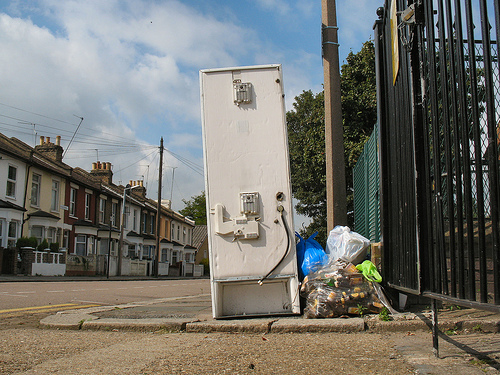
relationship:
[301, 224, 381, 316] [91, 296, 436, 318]
bag on sidewalk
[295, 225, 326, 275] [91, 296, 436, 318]
bag on sidewalk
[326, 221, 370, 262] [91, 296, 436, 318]
bag on sidewalk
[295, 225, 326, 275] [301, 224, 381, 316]
bag over bag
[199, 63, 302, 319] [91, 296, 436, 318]
box on sidewalk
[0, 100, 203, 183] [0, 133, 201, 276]
wires over homes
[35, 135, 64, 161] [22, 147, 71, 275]
chimney top of home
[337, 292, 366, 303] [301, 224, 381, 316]
bottle in bag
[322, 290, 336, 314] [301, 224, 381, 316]
bottle in bag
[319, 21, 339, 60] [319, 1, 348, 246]
sign strapped to pole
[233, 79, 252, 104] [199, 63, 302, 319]
control for box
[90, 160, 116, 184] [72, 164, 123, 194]
chimney on roof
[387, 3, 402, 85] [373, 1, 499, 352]
sign attached to fence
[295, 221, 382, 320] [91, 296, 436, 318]
trash on sidewalk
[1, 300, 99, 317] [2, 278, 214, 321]
line on street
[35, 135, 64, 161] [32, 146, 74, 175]
chimney on roof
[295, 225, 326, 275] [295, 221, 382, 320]
bag on pile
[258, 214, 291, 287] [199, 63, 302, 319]
cord on box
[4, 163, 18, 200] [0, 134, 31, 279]
window on home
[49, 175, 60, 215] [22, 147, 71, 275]
window on home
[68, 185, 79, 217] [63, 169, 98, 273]
window on home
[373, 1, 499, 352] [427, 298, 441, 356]
fence has support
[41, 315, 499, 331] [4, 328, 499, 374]
curb along driveway